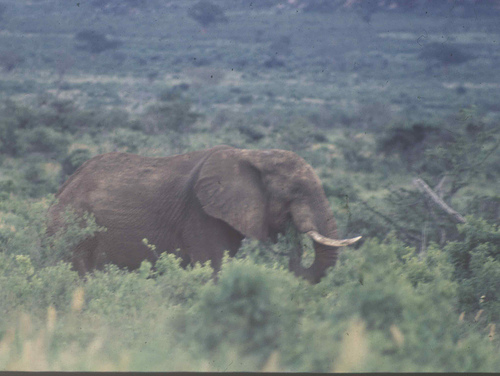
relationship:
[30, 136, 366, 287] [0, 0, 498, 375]
elephant in brush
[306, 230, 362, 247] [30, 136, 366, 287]
tusk on elephant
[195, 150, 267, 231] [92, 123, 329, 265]
ear on elephant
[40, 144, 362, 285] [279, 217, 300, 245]
elephant eating food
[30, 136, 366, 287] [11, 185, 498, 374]
elephant eating brush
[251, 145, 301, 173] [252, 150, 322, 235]
mud on head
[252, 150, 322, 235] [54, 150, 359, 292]
head of elephant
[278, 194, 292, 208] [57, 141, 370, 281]
eye of elephant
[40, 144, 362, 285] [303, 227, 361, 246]
elephant with tusk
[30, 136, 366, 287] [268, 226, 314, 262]
elephant placing leaves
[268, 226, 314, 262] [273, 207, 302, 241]
leaves placing in mouth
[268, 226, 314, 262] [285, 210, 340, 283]
leaves placing with trunk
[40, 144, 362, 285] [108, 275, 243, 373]
elephant in bushes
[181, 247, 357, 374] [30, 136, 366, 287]
shrubbery in front of elephant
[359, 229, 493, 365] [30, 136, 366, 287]
shrubbery in front of elephant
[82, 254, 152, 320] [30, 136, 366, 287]
shrubbery in front of elephant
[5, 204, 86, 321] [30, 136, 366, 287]
shrubbery in front of elephant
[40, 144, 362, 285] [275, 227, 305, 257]
elephant shoving plant life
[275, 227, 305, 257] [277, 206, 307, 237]
plant life in mouth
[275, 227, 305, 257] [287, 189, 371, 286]
plant life shoving with trunk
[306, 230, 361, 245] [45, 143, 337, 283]
tusk of elephant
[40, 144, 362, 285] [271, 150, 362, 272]
elephant with head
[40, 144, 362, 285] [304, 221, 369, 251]
elephant using trunk